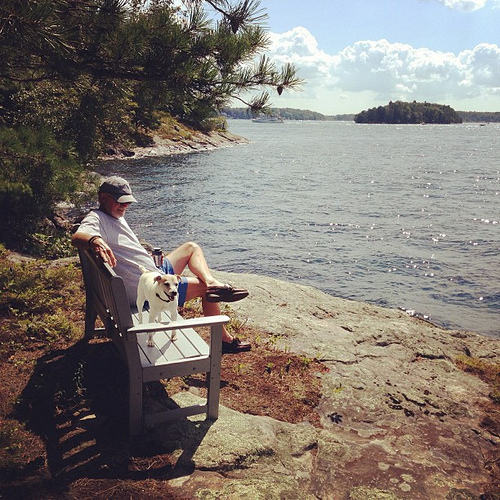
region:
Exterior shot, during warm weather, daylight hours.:
[8, 46, 498, 495]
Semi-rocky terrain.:
[284, 290, 459, 498]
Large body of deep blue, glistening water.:
[248, 119, 460, 263]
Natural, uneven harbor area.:
[42, 133, 486, 385]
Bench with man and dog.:
[81, 158, 260, 439]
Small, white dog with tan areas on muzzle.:
[141, 269, 188, 342]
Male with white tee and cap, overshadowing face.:
[84, 175, 157, 255]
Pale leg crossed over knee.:
[176, 245, 261, 357]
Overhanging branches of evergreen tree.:
[51, 45, 261, 135]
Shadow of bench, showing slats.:
[30, 337, 187, 489]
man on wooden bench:
[93, 149, 304, 333]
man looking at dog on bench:
[82, 193, 416, 408]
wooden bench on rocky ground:
[91, 324, 392, 442]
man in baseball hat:
[77, 173, 159, 253]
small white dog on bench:
[125, 256, 199, 339]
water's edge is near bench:
[180, 193, 438, 381]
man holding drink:
[134, 239, 174, 275]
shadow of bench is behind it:
[10, 328, 212, 475]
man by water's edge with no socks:
[192, 257, 256, 315]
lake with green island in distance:
[290, 72, 465, 261]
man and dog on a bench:
[67, 128, 263, 425]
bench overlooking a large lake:
[62, 85, 487, 360]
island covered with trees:
[330, 82, 475, 137]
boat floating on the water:
[236, 101, 311, 141]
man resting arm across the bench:
[70, 162, 141, 329]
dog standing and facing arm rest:
[125, 260, 200, 355]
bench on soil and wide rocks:
[20, 242, 471, 479]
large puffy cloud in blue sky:
[280, 25, 476, 95]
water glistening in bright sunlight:
[270, 115, 485, 281]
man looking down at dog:
[63, 160, 263, 360]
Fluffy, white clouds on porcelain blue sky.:
[281, 31, 475, 97]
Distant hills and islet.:
[241, 97, 495, 124]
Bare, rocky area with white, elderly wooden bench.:
[18, 181, 498, 479]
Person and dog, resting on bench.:
[78, 172, 238, 366]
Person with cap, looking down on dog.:
[100, 180, 144, 236]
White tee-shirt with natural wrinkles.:
[90, 220, 150, 276]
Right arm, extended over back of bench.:
[83, 220, 114, 270]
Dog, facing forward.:
[141, 272, 201, 352]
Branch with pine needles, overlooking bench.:
[12, 32, 299, 141]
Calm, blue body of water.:
[268, 144, 453, 271]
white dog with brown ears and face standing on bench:
[133, 269, 190, 344]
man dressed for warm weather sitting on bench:
[70, 177, 250, 361]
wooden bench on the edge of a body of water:
[75, 227, 232, 433]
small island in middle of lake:
[355, 97, 459, 124]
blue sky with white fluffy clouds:
[221, 0, 498, 113]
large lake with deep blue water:
[96, 116, 498, 326]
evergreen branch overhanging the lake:
[7, 4, 298, 120]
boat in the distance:
[253, 115, 290, 122]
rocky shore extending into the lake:
[8, 266, 498, 496]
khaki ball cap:
[98, 174, 135, 202]